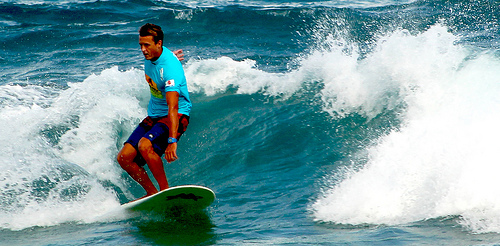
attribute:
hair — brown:
[134, 24, 164, 42]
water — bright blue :
[3, 3, 499, 238]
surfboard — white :
[129, 180, 217, 230]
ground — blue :
[356, 134, 438, 171]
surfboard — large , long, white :
[117, 182, 219, 224]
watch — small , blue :
[164, 132, 182, 151]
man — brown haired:
[92, 17, 210, 199]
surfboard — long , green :
[87, 168, 239, 235]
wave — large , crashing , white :
[13, 68, 100, 211]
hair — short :
[135, 21, 166, 45]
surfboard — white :
[115, 184, 217, 214]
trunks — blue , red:
[122, 113, 192, 167]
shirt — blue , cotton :
[135, 46, 194, 128]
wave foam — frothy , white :
[310, 11, 498, 236]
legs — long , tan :
[115, 142, 180, 192]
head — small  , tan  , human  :
[134, 20, 164, 62]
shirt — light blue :
[136, 63, 191, 113]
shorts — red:
[136, 110, 187, 169]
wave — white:
[1, 57, 142, 232]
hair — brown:
[135, 20, 165, 50]